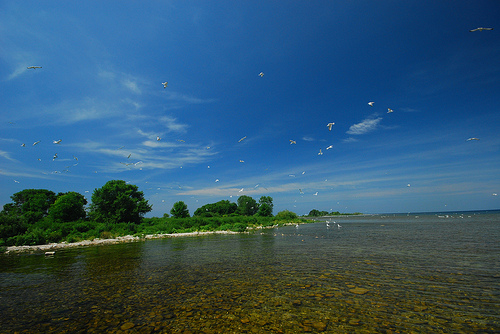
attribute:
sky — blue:
[254, 44, 344, 184]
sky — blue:
[303, 101, 417, 173]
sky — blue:
[251, 104, 386, 153]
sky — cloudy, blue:
[4, 4, 497, 212]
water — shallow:
[0, 210, 499, 330]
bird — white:
[364, 101, 376, 107]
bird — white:
[386, 109, 394, 115]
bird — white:
[466, 26, 492, 32]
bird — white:
[324, 120, 336, 132]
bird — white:
[287, 139, 299, 147]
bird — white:
[257, 70, 267, 80]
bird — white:
[159, 81, 169, 88]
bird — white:
[52, 140, 63, 147]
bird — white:
[159, 80, 169, 90]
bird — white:
[151, 137, 161, 146]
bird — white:
[23, 65, 43, 71]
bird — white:
[51, 140, 62, 145]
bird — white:
[50, 138, 62, 145]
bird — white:
[288, 140, 298, 148]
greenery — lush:
[0, 176, 363, 247]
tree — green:
[85, 178, 153, 222]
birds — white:
[264, 176, 343, 214]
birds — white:
[244, 216, 342, 240]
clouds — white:
[14, 54, 465, 208]